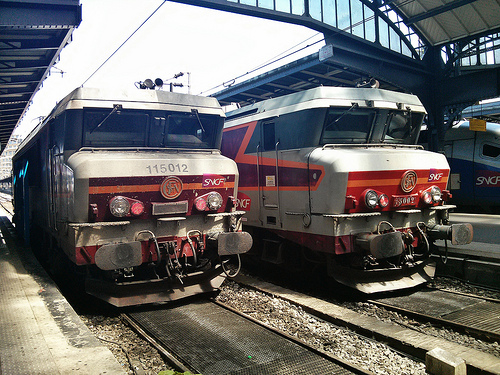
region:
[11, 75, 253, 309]
this train is on the left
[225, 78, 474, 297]
this train is on the right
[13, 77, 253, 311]
this trains front is red and orange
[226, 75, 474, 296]
this trains front is two colors of orange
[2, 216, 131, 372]
the sidewalk is grey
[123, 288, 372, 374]
the track is black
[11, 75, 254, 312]
the train is old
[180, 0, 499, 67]
the cover is made of glass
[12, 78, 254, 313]
the train is number 115012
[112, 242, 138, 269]
this has a skull on it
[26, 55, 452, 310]
Two trains are on the tracks.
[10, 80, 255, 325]
The train is grey, orange, and red.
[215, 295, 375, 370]
A metal rail on the train tracks.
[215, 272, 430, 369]
The gravel near the train is called track ballast.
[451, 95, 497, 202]
Another train is partially visible.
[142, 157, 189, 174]
The number 115012 is on front of the train.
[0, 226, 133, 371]
The train platform is next to the train.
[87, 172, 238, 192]
The train has an orange stripe.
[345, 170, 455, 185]
The train has a red stripe.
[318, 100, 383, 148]
A window on the front of the train.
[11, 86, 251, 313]
a red and white train engine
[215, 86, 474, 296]
a red and white train engine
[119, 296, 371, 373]
a set of train tracks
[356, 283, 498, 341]
a set of train tracks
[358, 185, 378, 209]
a train front headlight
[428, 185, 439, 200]
a train front headlight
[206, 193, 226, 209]
a train front headlight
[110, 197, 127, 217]
a train front headlight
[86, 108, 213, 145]
a train front windshield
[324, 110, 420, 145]
a train front windshield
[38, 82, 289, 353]
the train on the left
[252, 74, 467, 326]
the train on the right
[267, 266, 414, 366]
concrete divider between the train tracks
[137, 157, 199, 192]
numbers on train are 115012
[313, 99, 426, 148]
windshield of train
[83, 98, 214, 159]
the windshield of the train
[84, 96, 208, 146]
the train's windshield wipers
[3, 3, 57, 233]
metal overhang of the platform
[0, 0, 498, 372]
two trains in a train station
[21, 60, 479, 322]
two trains have the same colors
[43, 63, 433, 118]
roofs of trains are white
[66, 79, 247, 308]
front of train is white and red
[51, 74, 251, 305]
number in front of train is 115012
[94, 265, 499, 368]
gravel on side of railroad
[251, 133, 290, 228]
handles on side of door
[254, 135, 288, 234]
handles are color silver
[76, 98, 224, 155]
wipes on windshield of train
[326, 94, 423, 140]
wipes on windshield of train